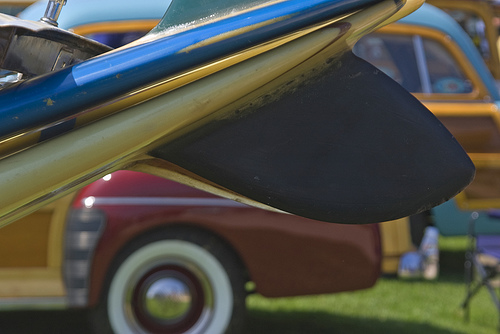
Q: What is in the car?
A: Surfboards.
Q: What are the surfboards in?
A: A car.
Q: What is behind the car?
A: Another car.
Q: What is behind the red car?
A: A chair.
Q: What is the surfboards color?
A: Blue and yellow.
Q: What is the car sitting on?
A: Green grass.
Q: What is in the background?
A: Blue car.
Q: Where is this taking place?
A: On a grassy field.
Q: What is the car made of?
A: Metal.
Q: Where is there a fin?
A: Surfboard.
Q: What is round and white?
A: Tire whitewall.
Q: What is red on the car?
A: Back fender.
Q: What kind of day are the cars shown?
A: Bright and sunny.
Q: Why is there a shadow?
A: Sun is shining.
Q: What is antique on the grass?
A: Cars.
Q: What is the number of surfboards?
A: Two.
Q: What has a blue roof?
A: Car in background.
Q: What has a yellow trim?
A: Car windows in background.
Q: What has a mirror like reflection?
A: Car hubcap.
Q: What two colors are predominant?
A: Blue and yellow.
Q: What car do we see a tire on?
A: The red car.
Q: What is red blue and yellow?
A: A car.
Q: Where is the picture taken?
A: A car show.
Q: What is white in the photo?
A: Sidewalls.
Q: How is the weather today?
A: Very nice.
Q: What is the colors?
A: Red and yellow.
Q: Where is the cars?
A: On the grass.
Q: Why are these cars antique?
A: Because of the year they were made.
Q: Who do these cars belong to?
A: The owners.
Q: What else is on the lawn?
A: A chair.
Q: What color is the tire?
A: Black and white.